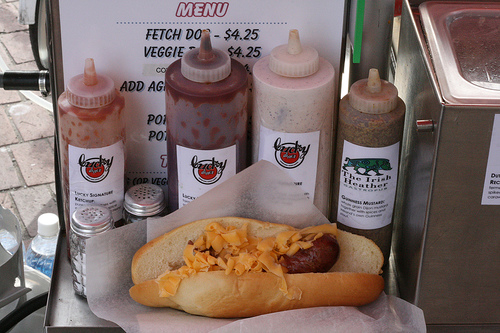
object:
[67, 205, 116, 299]
salt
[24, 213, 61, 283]
bottle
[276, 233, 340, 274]
hot dog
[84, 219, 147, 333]
wrapper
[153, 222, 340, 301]
cheese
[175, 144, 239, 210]
lable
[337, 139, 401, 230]
label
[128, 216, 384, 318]
bun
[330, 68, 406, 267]
bottle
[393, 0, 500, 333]
metal box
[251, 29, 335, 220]
condiment bottle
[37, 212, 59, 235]
top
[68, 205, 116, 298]
shaker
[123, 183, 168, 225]
shaker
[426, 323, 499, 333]
ground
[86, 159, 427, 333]
tissue paper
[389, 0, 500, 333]
bin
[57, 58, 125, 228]
hood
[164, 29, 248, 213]
bottles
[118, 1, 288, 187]
menu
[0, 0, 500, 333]
picture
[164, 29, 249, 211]
sauce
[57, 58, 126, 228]
bottle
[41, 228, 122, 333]
tray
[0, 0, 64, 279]
window